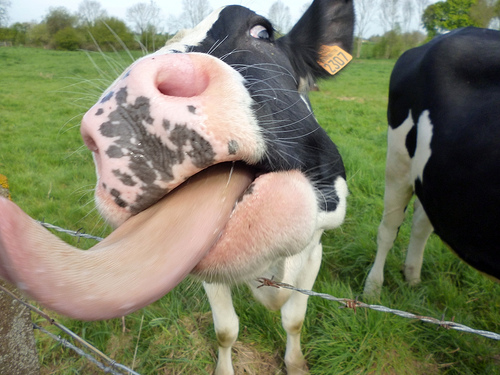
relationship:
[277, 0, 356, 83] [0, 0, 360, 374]
ear on cow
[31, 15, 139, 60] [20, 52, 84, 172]
trees in pasture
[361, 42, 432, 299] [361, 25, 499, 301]
back end on back`s cow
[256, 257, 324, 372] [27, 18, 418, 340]
leg on cow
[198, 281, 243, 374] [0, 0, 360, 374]
leg on cow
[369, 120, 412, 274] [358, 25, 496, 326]
back leg on cow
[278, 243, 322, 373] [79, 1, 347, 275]
leg on cow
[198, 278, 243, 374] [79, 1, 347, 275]
leg on cow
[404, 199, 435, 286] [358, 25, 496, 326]
leg on cow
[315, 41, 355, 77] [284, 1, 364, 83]
orange tag on ear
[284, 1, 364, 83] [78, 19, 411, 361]
ear on cow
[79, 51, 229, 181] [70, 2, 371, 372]
nose on cow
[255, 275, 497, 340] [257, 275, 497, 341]
barbed wire on fence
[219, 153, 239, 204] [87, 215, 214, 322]
slobber on tongue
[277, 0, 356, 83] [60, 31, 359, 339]
ear on cow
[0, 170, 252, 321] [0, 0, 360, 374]
tongue on cow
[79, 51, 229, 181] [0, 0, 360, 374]
nose on cow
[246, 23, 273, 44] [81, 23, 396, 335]
eye on cow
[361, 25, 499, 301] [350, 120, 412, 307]
back`s cow has back leg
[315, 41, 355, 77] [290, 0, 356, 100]
orange tag on ear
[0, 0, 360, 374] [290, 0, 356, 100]
cow has ear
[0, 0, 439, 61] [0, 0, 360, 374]
bushes are behind cow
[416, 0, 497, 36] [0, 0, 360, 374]
trees are behind cow